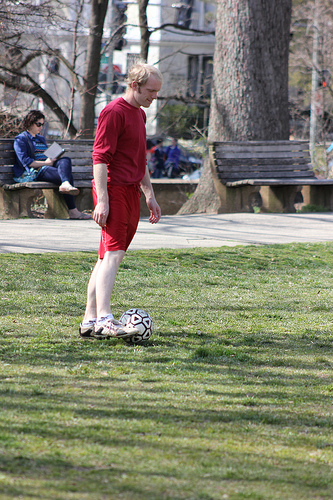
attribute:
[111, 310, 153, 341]
ball — soccer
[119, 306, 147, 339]
ball — soccer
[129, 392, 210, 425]
grass — green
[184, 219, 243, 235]
sidewalk — paved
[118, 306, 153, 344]
soccer ball — white, black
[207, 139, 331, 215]
bench — empty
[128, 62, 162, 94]
hair — blonde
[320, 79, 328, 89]
light — red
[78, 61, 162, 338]
player — Soccer player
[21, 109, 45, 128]
hair — dark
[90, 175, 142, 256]
shorts — red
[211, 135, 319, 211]
park bench — wooden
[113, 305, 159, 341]
ball — white, black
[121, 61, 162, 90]
hair — blonde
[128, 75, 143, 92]
man's ear — red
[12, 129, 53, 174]
woman's jacket — blue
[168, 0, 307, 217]
tree — old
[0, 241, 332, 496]
grass — green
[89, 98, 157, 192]
man's shirt — red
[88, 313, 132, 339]
shoe — white